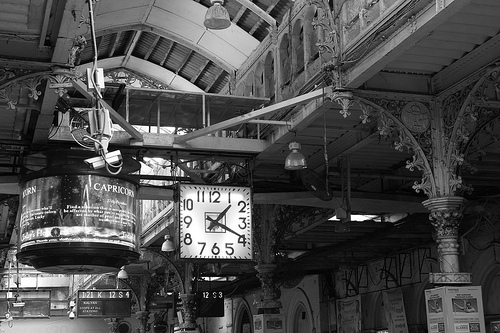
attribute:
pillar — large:
[419, 195, 475, 287]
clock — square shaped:
[169, 179, 259, 269]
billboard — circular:
[10, 156, 151, 291]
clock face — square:
[163, 178, 262, 265]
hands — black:
[204, 201, 243, 239]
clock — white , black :
[142, 168, 308, 312]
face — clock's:
[179, 185, 255, 259]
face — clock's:
[165, 176, 260, 265]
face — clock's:
[164, 180, 263, 270]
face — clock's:
[171, 180, 261, 263]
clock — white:
[170, 180, 266, 264]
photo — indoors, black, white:
[2, 1, 483, 314]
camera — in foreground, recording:
[70, 3, 127, 173]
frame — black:
[170, 180, 185, 259]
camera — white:
[81, 143, 127, 175]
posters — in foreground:
[417, 278, 483, 331]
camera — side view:
[74, 147, 128, 178]